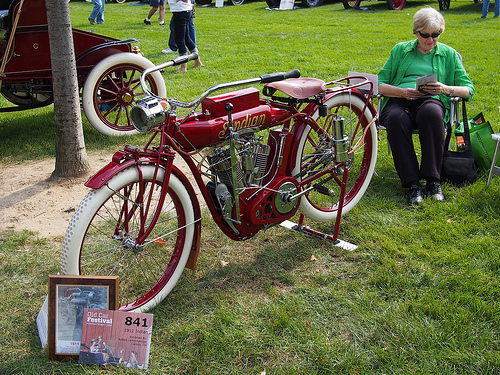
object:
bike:
[60, 51, 381, 320]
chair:
[370, 96, 461, 187]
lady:
[373, 4, 474, 207]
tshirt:
[396, 50, 439, 100]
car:
[1, 0, 169, 139]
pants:
[379, 101, 444, 187]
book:
[80, 308, 153, 369]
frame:
[46, 274, 119, 361]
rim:
[299, 100, 373, 212]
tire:
[60, 165, 194, 314]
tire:
[296, 94, 378, 223]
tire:
[82, 51, 167, 138]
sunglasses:
[413, 30, 442, 39]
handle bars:
[139, 50, 198, 99]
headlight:
[128, 95, 165, 133]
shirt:
[375, 39, 474, 123]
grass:
[0, 1, 498, 375]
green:
[439, 240, 462, 275]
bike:
[44, 47, 431, 300]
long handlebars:
[170, 68, 302, 108]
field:
[0, 0, 499, 375]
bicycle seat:
[264, 77, 329, 101]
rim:
[81, 175, 187, 311]